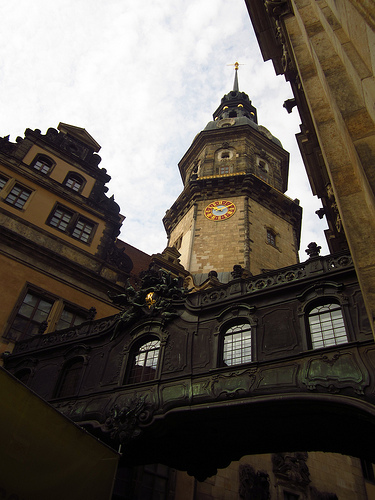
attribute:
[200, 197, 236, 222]
clock — large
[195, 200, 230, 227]
clock — multi colored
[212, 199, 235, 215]
hand — is gold